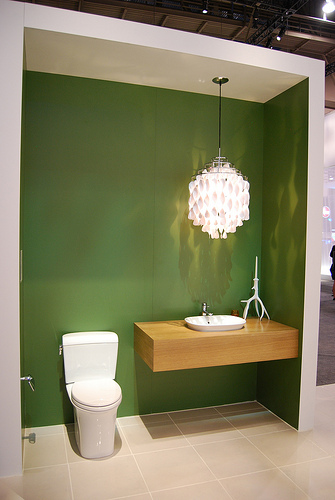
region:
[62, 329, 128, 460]
a white toilet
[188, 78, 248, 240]
a hanging light fixture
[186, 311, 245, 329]
a white bathroom sink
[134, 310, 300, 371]
a wooden bathroom counter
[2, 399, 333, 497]
a light colored tile floor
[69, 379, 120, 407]
a white toilet lid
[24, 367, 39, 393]
silver toilet paper holder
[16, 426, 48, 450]
shadow on floor from toilet paper holder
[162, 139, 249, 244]
chandelier hanging above the vanity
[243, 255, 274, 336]
art sitting on the vanity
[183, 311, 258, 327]
bowl for the vanity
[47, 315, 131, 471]
modern sleek white toilet in bathroom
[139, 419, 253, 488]
large tiles on the bathroom floor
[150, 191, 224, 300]
light cast on wall from chandelier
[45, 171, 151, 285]
green moss walls of bathroom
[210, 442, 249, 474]
man surfing on a white surfboardman surfing on a white surfboardman surfing on a white surfboard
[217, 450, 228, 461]
man surfing on a white surfboardman surfing on a white surfboardman surfing on a white surfboard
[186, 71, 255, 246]
A chandelier hangs over the sink.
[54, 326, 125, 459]
a white toilet.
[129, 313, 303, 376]
A wood shelf with a sink on it.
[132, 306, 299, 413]
A hanging wooden shelf.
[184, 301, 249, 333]
A white sink on a wood shelf.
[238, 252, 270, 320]
A white decoration on the counter.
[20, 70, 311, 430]
The walls are green.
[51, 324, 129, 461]
The toilet seat lid is closed.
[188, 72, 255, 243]
The lamp over the sink is on.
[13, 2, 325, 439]
The bathroom is a display in a store.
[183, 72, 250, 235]
The hanging light over the sink.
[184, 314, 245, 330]
The basin of the sink.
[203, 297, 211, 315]
The faucet of the sink.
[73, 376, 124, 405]
The toilet lid of the toilet.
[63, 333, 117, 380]
The water tank of the toilet.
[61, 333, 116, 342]
The lid of the water tank.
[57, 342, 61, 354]
The handle to flush the toilet.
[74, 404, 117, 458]
The base of the toilet.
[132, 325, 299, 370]
The wooden counter of the sink.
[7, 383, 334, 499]
The tiles of the floor.